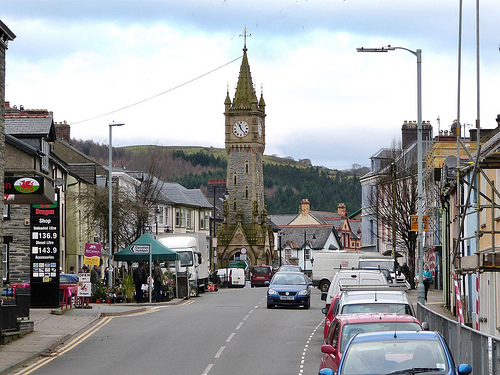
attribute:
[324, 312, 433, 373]
car — red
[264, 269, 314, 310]
car — blue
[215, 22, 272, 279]
tower — tan block, clock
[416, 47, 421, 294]
pole — silver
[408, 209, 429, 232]
sign — yellow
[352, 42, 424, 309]
light — overhead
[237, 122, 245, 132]
hands — black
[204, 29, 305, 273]
tower — white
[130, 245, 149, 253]
sign — black, white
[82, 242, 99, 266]
sign — white, black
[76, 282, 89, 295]
sign — white, black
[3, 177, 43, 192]
sign — white, black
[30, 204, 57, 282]
sign — white, black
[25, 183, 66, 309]
sign — price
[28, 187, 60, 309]
sign — tall, black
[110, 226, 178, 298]
tent — green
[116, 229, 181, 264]
tent top — green, fabric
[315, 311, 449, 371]
car — red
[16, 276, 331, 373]
street — paved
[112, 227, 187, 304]
tent — green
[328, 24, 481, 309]
pole — tall, grey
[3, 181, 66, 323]
station — gas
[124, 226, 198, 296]
tent — green 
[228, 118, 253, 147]
clock — white, black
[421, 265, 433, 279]
shirt — blue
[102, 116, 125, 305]
street light — overhead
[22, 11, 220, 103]
sky — cloudy, blue